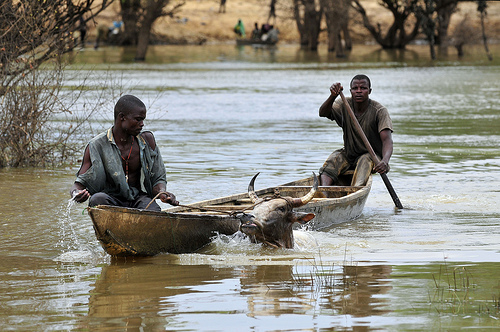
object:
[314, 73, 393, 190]
man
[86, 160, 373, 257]
kayak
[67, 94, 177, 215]
man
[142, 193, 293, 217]
leash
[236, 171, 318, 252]
cow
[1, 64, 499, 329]
water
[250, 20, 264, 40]
person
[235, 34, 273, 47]
boat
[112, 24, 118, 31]
shirt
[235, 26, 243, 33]
shirt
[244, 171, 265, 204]
horn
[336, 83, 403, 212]
paddle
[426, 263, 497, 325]
grass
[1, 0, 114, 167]
tree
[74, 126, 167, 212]
clothes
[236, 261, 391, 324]
reflection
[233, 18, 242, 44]
person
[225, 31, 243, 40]
grass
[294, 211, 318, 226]
ear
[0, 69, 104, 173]
brush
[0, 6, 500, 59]
shore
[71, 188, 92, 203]
hand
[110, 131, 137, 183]
necklace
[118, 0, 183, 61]
tree